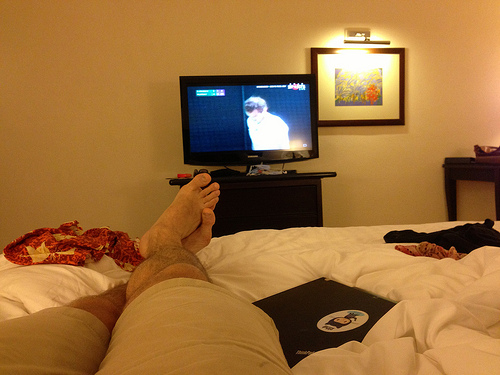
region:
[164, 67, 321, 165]
flat screen black television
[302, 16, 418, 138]
painting illuminated by light on wall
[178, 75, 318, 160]
television is turned on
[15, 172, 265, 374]
legs of person lying in bed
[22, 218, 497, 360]
blanket on bed is white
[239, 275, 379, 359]
laptop has a sticker on front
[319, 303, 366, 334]
circle shaped sticker with girl figure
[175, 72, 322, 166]
tennis match is on the television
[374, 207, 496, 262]
articles of clothing on the bed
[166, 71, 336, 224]
television is on a black stand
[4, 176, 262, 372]
man has hairy legs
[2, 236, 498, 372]
man laying on the bed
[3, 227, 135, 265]
clothes are on the bed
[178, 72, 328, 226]
man is watching television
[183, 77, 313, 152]
there is a tennis match on TV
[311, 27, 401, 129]
picture frame on wall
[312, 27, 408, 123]
picture frame has a light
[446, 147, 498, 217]
table next to the television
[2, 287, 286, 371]
man wearing beige shorts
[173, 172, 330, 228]
television on a black stand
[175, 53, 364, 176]
the tv is on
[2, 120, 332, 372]
man's legs stretched out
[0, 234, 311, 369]
man is wearing brown shorts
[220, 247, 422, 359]
black laptop on bed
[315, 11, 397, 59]
light above picture frame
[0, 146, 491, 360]
man is laying on bed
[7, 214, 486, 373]
bed comforter is white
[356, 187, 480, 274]
clothes laying on bed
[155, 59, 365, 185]
the tv is black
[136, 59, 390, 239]
tv is on tv stand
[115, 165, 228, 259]
feet are on the bed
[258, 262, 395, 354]
a black book is on the bed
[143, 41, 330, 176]
the television is on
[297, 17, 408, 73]
the light is on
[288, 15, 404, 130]
the light is over the picture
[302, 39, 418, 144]
the picture frame is brown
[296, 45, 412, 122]
the picture frame is made of wood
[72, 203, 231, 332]
the legs are hairy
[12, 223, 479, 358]
the comforter is white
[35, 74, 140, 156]
yellow walls in the back ground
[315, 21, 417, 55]
bright light over picture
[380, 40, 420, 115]
brown frame on small picture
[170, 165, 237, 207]
white toes on mans' foot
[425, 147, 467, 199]
feet on brown table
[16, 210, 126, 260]
red and white clothing on bed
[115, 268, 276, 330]
seam in tan pants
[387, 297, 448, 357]
wrinkles in white blanket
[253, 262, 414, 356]
black book laying on bed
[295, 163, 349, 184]
black edge of television table